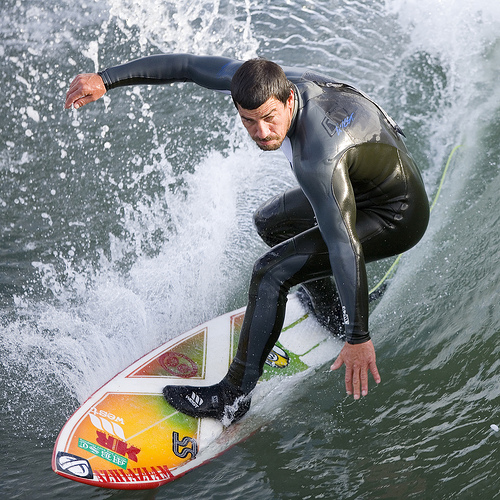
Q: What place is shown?
A: It is an ocean.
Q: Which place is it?
A: It is an ocean.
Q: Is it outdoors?
A: Yes, it is outdoors.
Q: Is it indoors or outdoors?
A: It is outdoors.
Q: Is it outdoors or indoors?
A: It is outdoors.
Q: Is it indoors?
A: No, it is outdoors.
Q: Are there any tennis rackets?
A: No, there are no tennis rackets.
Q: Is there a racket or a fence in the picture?
A: No, there are no rackets or fences.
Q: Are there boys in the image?
A: No, there are no boys.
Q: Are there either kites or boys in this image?
A: No, there are no boys or kites.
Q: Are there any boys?
A: No, there are no boys.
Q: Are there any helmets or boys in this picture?
A: No, there are no boys or helmets.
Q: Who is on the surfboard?
A: The man is on the surfboard.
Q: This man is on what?
A: The man is on the surfboard.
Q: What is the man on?
A: The man is on the surfboard.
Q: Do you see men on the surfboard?
A: Yes, there is a man on the surfboard.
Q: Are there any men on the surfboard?
A: Yes, there is a man on the surfboard.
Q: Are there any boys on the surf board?
A: No, there is a man on the surf board.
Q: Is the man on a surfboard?
A: Yes, the man is on a surfboard.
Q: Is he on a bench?
A: No, the man is on a surfboard.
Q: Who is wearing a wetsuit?
A: The man is wearing a wetsuit.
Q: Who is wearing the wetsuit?
A: The man is wearing a wetsuit.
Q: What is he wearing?
A: The man is wearing a wetsuit.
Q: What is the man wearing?
A: The man is wearing a wetsuit.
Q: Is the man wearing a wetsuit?
A: Yes, the man is wearing a wetsuit.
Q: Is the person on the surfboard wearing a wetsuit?
A: Yes, the man is wearing a wetsuit.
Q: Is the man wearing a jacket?
A: No, the man is wearing a wetsuit.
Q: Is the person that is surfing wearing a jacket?
A: No, the man is wearing a wetsuit.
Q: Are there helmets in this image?
A: No, there are no helmets.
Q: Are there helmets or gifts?
A: No, there are no helmets or gifts.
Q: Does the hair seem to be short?
A: Yes, the hair is short.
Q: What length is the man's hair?
A: The hair is short.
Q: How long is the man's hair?
A: The hair is short.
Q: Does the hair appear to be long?
A: No, the hair is short.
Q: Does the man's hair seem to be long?
A: No, the hair is short.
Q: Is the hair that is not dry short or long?
A: The hair is short.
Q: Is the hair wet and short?
A: Yes, the hair is wet and short.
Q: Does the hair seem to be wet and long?
A: No, the hair is wet but short.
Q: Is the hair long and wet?
A: No, the hair is wet but short.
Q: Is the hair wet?
A: Yes, the hair is wet.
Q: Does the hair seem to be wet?
A: Yes, the hair is wet.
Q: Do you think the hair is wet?
A: Yes, the hair is wet.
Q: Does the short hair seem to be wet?
A: Yes, the hair is wet.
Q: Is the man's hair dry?
A: No, the hair is wet.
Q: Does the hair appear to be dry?
A: No, the hair is wet.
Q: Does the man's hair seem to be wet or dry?
A: The hair is wet.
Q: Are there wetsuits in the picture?
A: Yes, there is a wetsuit.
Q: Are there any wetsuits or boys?
A: Yes, there is a wetsuit.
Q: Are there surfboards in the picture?
A: Yes, there is a surfboard.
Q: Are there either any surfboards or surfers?
A: Yes, there is a surfboard.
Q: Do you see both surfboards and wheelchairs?
A: No, there is a surfboard but no wheelchairs.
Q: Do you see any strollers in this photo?
A: No, there are no strollers.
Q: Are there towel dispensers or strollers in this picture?
A: No, there are no strollers or towel dispensers.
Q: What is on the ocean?
A: The surf board is on the ocean.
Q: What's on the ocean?
A: The surf board is on the ocean.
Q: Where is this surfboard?
A: The surfboard is on the ocean.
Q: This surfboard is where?
A: The surfboard is on the ocean.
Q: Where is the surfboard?
A: The surfboard is on the ocean.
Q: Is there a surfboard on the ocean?
A: Yes, there is a surfboard on the ocean.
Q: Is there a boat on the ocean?
A: No, there is a surfboard on the ocean.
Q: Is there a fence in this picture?
A: No, there are no fences.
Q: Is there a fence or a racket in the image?
A: No, there are no fences or rackets.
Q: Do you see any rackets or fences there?
A: No, there are no fences or rackets.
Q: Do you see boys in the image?
A: No, there are no boys.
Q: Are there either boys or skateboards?
A: No, there are no boys or skateboards.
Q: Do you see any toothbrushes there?
A: No, there are no toothbrushes.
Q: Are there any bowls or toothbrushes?
A: No, there are no toothbrushes or bowls.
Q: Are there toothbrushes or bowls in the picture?
A: No, there are no toothbrushes or bowls.